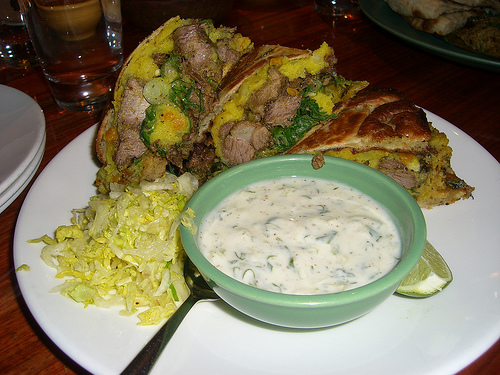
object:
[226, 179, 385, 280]
curd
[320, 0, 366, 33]
glasses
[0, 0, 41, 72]
glasses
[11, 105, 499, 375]
dish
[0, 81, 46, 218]
dish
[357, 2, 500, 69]
dish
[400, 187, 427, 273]
edge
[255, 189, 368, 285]
milk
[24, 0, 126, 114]
glass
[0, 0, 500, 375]
ground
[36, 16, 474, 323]
food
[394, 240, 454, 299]
lemon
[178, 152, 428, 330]
bowl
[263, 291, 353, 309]
edge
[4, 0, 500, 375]
table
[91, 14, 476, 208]
sandwich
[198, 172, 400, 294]
soup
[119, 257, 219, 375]
spoon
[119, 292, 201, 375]
handle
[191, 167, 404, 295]
sauce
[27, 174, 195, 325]
cabbage